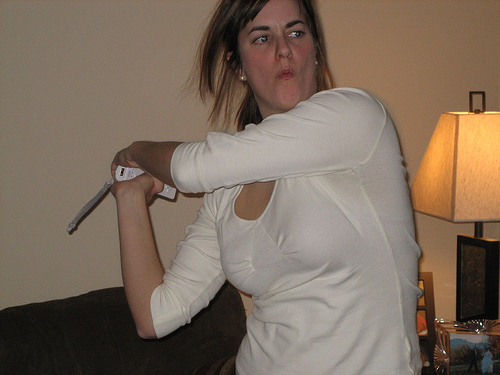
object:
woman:
[109, 0, 426, 374]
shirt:
[148, 86, 424, 374]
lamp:
[409, 91, 499, 226]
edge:
[424, 272, 435, 366]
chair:
[413, 270, 434, 373]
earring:
[313, 60, 319, 65]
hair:
[175, 0, 338, 130]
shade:
[409, 111, 499, 223]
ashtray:
[450, 317, 499, 335]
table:
[426, 324, 498, 373]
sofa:
[0, 279, 252, 374]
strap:
[63, 182, 114, 234]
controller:
[113, 163, 176, 199]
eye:
[286, 28, 307, 41]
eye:
[251, 33, 271, 45]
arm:
[128, 89, 384, 193]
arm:
[113, 195, 223, 339]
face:
[235, 0, 316, 111]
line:
[360, 103, 386, 174]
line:
[353, 169, 415, 373]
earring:
[237, 68, 251, 82]